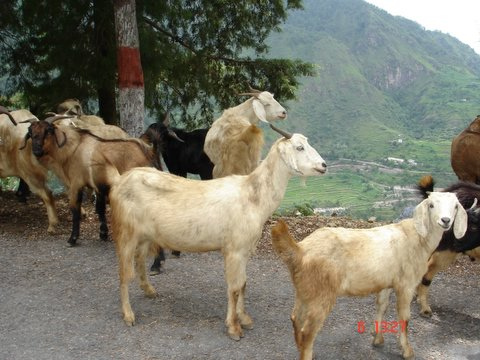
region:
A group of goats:
[0, 83, 478, 359]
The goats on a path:
[0, 89, 479, 359]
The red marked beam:
[117, 0, 145, 140]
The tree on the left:
[0, 0, 320, 134]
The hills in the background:
[0, 0, 479, 216]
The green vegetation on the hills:
[0, 0, 478, 220]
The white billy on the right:
[271, 186, 475, 357]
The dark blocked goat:
[143, 118, 219, 178]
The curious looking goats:
[1, 0, 478, 359]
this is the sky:
[427, 2, 455, 22]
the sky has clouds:
[403, 0, 412, 12]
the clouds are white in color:
[402, 1, 431, 16]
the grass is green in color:
[320, 183, 339, 196]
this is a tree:
[21, 4, 246, 107]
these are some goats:
[17, 82, 467, 354]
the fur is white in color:
[174, 222, 199, 230]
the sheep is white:
[105, 134, 323, 333]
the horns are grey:
[268, 119, 290, 140]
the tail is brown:
[269, 223, 307, 263]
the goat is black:
[159, 112, 208, 181]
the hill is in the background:
[302, 27, 468, 133]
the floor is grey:
[20, 282, 102, 357]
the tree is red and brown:
[103, 30, 151, 120]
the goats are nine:
[8, 96, 476, 336]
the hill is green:
[272, 28, 477, 108]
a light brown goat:
[270, 189, 467, 357]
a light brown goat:
[108, 124, 328, 342]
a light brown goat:
[200, 87, 288, 190]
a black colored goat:
[140, 112, 242, 201]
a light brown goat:
[20, 112, 160, 247]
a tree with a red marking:
[105, 0, 150, 231]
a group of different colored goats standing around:
[0, 80, 477, 354]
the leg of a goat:
[109, 238, 139, 325]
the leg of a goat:
[225, 257, 245, 343]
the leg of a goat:
[393, 285, 419, 359]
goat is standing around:
[109, 122, 325, 342]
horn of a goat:
[268, 123, 289, 138]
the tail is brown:
[268, 221, 302, 258]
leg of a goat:
[299, 295, 331, 358]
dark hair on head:
[25, 122, 49, 150]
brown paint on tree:
[115, 44, 142, 89]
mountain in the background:
[141, 0, 477, 155]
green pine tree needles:
[0, 0, 316, 111]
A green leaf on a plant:
[219, 9, 221, 13]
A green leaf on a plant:
[205, 69, 206, 73]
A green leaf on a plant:
[283, 65, 287, 67]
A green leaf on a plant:
[261, 66, 263, 68]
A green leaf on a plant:
[273, 83, 274, 84]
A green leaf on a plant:
[46, 46, 50, 48]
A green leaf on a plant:
[46, 7, 48, 8]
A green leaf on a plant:
[214, 13, 216, 15]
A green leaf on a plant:
[156, 44, 158, 46]